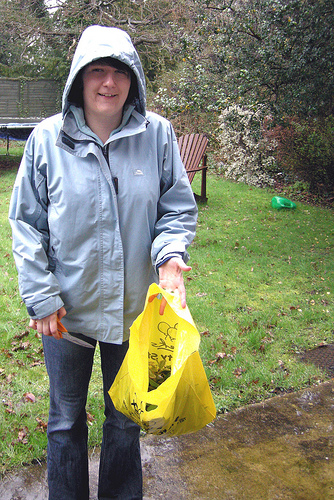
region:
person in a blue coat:
[14, 22, 212, 362]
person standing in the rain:
[2, 15, 288, 483]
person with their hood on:
[22, 28, 193, 199]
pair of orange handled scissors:
[26, 283, 111, 364]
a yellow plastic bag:
[97, 264, 245, 455]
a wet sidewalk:
[193, 298, 332, 491]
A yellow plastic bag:
[100, 283, 217, 437]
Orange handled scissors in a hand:
[46, 319, 96, 350]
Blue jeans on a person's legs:
[31, 326, 141, 498]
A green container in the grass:
[267, 193, 302, 214]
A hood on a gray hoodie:
[54, 23, 149, 136]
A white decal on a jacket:
[131, 166, 146, 176]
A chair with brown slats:
[170, 131, 208, 201]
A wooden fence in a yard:
[0, 74, 62, 121]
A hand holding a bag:
[142, 251, 193, 312]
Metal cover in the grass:
[298, 338, 332, 369]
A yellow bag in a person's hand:
[107, 282, 214, 440]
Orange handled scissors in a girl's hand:
[41, 316, 93, 349]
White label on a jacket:
[133, 167, 142, 176]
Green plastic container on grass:
[270, 194, 296, 209]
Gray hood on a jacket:
[60, 26, 149, 125]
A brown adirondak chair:
[177, 132, 208, 203]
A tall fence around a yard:
[1, 77, 59, 115]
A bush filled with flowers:
[214, 104, 280, 189]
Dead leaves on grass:
[208, 349, 248, 378]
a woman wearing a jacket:
[67, 39, 148, 170]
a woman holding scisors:
[29, 302, 108, 368]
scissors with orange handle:
[26, 302, 88, 352]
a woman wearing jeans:
[29, 304, 147, 495]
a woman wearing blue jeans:
[46, 294, 184, 497]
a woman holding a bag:
[78, 270, 241, 455]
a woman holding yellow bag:
[58, 268, 229, 442]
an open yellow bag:
[108, 276, 224, 444]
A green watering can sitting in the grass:
[267, 193, 297, 213]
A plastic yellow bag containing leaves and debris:
[105, 279, 218, 440]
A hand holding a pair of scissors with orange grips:
[26, 299, 97, 351]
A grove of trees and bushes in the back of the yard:
[2, 2, 332, 211]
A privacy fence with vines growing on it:
[1, 74, 68, 132]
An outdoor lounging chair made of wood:
[151, 130, 211, 206]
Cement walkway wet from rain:
[9, 380, 333, 498]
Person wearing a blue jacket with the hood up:
[6, 24, 191, 344]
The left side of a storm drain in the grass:
[301, 340, 332, 375]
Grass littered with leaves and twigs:
[2, 153, 330, 455]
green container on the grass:
[269, 195, 296, 209]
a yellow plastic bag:
[108, 282, 217, 436]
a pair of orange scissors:
[49, 319, 93, 351]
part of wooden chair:
[176, 135, 205, 201]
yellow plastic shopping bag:
[97, 277, 220, 442]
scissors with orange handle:
[21, 311, 95, 356]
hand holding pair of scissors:
[24, 301, 97, 357]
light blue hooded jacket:
[8, 21, 200, 351]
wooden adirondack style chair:
[171, 128, 212, 208]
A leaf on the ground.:
[213, 351, 228, 357]